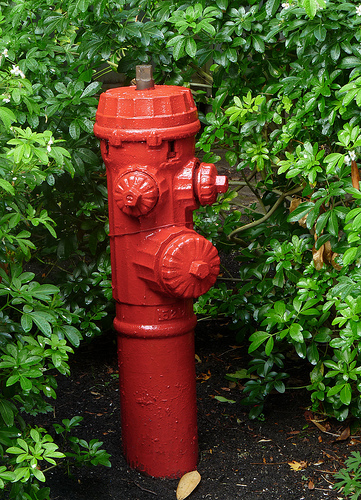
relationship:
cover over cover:
[158, 234, 219, 298] [158, 234, 219, 298]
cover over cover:
[198, 161, 227, 198] [198, 162, 229, 207]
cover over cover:
[114, 171, 158, 217] [114, 171, 158, 217]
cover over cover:
[98, 80, 200, 136] [94, 84, 201, 136]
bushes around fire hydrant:
[1, 0, 359, 498] [93, 64, 230, 477]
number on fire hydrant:
[151, 304, 187, 320] [93, 64, 230, 477]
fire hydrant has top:
[93, 64, 230, 477] [93, 64, 198, 129]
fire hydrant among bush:
[93, 64, 229, 477] [187, 40, 358, 430]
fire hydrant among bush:
[93, 64, 229, 477] [1, 0, 132, 488]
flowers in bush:
[2, 43, 32, 83] [187, 40, 358, 430]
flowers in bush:
[2, 43, 32, 83] [1, 0, 132, 488]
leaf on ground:
[150, 463, 209, 496] [15, 321, 354, 498]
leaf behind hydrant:
[244, 336, 272, 356] [62, 31, 293, 415]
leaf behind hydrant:
[262, 332, 277, 359] [62, 31, 293, 415]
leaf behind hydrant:
[29, 312, 54, 336] [62, 31, 293, 415]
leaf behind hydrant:
[21, 365, 48, 384] [62, 31, 293, 415]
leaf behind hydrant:
[283, 160, 308, 184] [62, 31, 293, 415]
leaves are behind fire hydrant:
[245, 10, 356, 188] [93, 64, 229, 477]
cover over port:
[114, 167, 158, 219] [99, 165, 154, 209]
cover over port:
[77, 128, 168, 206] [100, 166, 188, 240]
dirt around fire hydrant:
[171, 429, 242, 460] [93, 64, 229, 477]